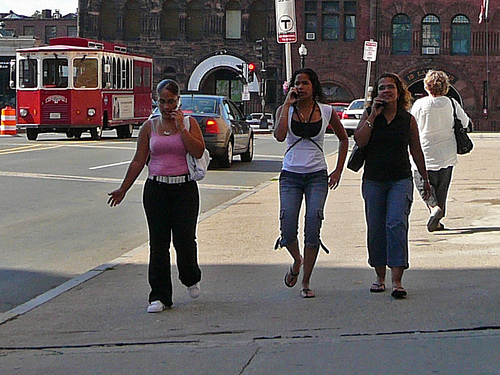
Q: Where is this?
A: This is at the sidewalk.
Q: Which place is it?
A: It is a sidewalk.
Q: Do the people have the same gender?
A: Yes, all the people are female.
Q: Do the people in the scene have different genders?
A: No, all the people are female.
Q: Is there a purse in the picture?
A: Yes, there is a purse.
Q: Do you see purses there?
A: Yes, there is a purse.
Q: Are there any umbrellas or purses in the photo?
A: Yes, there is a purse.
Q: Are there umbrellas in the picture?
A: No, there are no umbrellas.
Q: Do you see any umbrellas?
A: No, there are no umbrellas.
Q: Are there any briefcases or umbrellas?
A: No, there are no umbrellas or briefcases.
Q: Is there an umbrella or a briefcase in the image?
A: No, there are no umbrellas or briefcases.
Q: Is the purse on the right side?
A: Yes, the purse is on the right of the image.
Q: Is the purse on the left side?
A: No, the purse is on the right of the image.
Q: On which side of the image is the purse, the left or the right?
A: The purse is on the right of the image.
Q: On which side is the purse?
A: The purse is on the right of the image.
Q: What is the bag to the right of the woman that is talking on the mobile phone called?
A: The bag is a purse.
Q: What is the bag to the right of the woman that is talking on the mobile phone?
A: The bag is a purse.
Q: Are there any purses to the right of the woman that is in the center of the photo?
A: Yes, there is a purse to the right of the woman.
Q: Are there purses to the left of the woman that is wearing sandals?
A: No, the purse is to the right of the woman.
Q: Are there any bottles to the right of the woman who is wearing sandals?
A: No, there is a purse to the right of the woman.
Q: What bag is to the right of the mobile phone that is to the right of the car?
A: The bag is a purse.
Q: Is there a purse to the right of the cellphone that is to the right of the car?
A: Yes, there is a purse to the right of the cellphone.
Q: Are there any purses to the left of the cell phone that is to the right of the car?
A: No, the purse is to the right of the mobile phone.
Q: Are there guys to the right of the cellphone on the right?
A: No, there is a purse to the right of the mobile phone.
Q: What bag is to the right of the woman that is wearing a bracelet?
A: The bag is a purse.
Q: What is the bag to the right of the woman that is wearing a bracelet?
A: The bag is a purse.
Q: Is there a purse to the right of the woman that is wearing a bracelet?
A: Yes, there is a purse to the right of the woman.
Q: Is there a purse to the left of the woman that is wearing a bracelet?
A: No, the purse is to the right of the woman.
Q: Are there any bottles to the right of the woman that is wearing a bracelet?
A: No, there is a purse to the right of the woman.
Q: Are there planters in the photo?
A: No, there are no planters.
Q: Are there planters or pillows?
A: No, there are no planters or pillows.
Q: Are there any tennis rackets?
A: No, there are no tennis rackets.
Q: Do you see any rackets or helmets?
A: No, there are no rackets or helmets.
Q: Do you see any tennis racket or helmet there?
A: No, there are no rackets or helmets.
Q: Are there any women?
A: Yes, there is a woman.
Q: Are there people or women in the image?
A: Yes, there is a woman.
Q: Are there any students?
A: No, there are no students.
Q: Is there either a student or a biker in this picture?
A: No, there are no students or bikers.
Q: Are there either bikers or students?
A: No, there are no students or bikers.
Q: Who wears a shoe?
A: The woman wears a shoe.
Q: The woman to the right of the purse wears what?
A: The woman wears a shoe.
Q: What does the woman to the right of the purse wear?
A: The woman wears a shoe.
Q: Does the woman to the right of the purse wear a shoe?
A: Yes, the woman wears a shoe.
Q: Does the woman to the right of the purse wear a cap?
A: No, the woman wears a shoe.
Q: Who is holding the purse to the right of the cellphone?
A: The woman is holding the purse.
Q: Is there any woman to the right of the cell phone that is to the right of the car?
A: Yes, there is a woman to the right of the mobile phone.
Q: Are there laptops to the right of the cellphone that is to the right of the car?
A: No, there is a woman to the right of the mobile phone.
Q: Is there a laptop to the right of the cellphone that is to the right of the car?
A: No, there is a woman to the right of the mobile phone.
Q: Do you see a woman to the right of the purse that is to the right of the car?
A: Yes, there is a woman to the right of the purse.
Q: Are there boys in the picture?
A: No, there are no boys.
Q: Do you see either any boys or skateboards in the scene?
A: No, there are no boys or skateboards.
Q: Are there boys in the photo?
A: No, there are no boys.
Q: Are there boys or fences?
A: No, there are no boys or fences.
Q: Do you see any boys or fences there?
A: No, there are no boys or fences.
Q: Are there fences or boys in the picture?
A: No, there are no boys or fences.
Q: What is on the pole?
A: The sign is on the pole.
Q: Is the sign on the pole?
A: Yes, the sign is on the pole.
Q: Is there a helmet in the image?
A: No, there are no helmets.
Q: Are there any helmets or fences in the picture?
A: No, there are no helmets or fences.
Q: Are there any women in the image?
A: Yes, there is a woman.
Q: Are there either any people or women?
A: Yes, there is a woman.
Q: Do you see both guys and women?
A: No, there is a woman but no guys.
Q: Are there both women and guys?
A: No, there is a woman but no guys.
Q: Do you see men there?
A: No, there are no men.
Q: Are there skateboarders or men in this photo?
A: No, there are no men or skateboarders.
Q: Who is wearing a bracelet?
A: The woman is wearing a bracelet.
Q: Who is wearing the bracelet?
A: The woman is wearing a bracelet.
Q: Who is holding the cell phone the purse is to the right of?
A: The woman is holding the cell phone.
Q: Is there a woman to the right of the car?
A: Yes, there is a woman to the right of the car.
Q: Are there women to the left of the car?
A: No, the woman is to the right of the car.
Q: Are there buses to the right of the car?
A: No, there is a woman to the right of the car.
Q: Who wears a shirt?
A: The woman wears a shirt.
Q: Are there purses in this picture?
A: Yes, there is a purse.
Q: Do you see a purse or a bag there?
A: Yes, there is a purse.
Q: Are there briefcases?
A: No, there are no briefcases.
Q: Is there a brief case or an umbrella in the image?
A: No, there are no briefcases or umbrellas.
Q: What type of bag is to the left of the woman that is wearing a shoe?
A: The bag is a purse.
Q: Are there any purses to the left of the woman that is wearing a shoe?
A: Yes, there is a purse to the left of the woman.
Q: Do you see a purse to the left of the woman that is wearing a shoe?
A: Yes, there is a purse to the left of the woman.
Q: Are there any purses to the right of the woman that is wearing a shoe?
A: No, the purse is to the left of the woman.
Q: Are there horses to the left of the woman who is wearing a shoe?
A: No, there is a purse to the left of the woman.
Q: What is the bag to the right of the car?
A: The bag is a purse.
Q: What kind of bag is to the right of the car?
A: The bag is a purse.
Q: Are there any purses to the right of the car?
A: Yes, there is a purse to the right of the car.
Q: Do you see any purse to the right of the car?
A: Yes, there is a purse to the right of the car.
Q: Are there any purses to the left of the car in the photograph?
A: No, the purse is to the right of the car.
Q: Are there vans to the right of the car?
A: No, there is a purse to the right of the car.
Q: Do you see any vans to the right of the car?
A: No, there is a purse to the right of the car.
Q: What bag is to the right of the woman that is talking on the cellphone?
A: The bag is a purse.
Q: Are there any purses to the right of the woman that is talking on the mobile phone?
A: Yes, there is a purse to the right of the woman.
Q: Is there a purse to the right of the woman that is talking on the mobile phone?
A: Yes, there is a purse to the right of the woman.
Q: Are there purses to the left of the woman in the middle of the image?
A: No, the purse is to the right of the woman.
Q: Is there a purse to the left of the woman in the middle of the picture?
A: No, the purse is to the right of the woman.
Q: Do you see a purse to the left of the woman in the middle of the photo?
A: No, the purse is to the right of the woman.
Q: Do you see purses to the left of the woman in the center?
A: No, the purse is to the right of the woman.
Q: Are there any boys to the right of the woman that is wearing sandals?
A: No, there is a purse to the right of the woman.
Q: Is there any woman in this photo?
A: Yes, there is a woman.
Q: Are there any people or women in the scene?
A: Yes, there is a woman.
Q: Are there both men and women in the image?
A: No, there is a woman but no men.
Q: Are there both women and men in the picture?
A: No, there is a woman but no men.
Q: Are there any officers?
A: No, there are no officers.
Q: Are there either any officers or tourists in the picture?
A: No, there are no officers or tourists.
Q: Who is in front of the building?
A: The woman is in front of the building.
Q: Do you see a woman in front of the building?
A: Yes, there is a woman in front of the building.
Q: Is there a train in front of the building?
A: No, there is a woman in front of the building.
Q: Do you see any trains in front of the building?
A: No, there is a woman in front of the building.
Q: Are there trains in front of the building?
A: No, there is a woman in front of the building.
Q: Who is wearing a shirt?
A: The woman is wearing a shirt.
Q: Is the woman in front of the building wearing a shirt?
A: Yes, the woman is wearing a shirt.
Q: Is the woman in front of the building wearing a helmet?
A: No, the woman is wearing a shirt.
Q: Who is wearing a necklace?
A: The woman is wearing a necklace.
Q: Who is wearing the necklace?
A: The woman is wearing a necklace.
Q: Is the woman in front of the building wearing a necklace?
A: Yes, the woman is wearing a necklace.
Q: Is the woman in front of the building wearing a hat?
A: No, the woman is wearing a necklace.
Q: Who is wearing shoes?
A: The woman is wearing shoes.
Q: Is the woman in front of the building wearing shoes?
A: Yes, the woman is wearing shoes.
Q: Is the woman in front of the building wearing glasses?
A: No, the woman is wearing shoes.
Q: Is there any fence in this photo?
A: No, there are no fences.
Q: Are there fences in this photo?
A: No, there are no fences.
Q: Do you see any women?
A: Yes, there is a woman.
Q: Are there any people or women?
A: Yes, there is a woman.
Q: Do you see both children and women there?
A: No, there is a woman but no children.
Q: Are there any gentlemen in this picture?
A: No, there are no gentlemen.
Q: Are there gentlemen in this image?
A: No, there are no gentlemen.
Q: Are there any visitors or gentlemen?
A: No, there are no gentlemen or visitors.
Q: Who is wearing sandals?
A: The woman is wearing sandals.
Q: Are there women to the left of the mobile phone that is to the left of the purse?
A: Yes, there is a woman to the left of the cell phone.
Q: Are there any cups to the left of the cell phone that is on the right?
A: No, there is a woman to the left of the cell phone.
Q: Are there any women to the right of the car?
A: Yes, there is a woman to the right of the car.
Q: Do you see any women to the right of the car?
A: Yes, there is a woman to the right of the car.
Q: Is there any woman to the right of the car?
A: Yes, there is a woman to the right of the car.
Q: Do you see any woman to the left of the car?
A: No, the woman is to the right of the car.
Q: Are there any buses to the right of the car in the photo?
A: No, there is a woman to the right of the car.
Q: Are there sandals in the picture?
A: Yes, there are sandals.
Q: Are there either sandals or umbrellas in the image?
A: Yes, there are sandals.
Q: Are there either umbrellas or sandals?
A: Yes, there are sandals.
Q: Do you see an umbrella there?
A: No, there are no umbrellas.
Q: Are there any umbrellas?
A: No, there are no umbrellas.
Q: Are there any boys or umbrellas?
A: No, there are no umbrellas or boys.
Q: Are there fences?
A: No, there are no fences.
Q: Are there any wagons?
A: No, there are no wagons.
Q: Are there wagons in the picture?
A: No, there are no wagons.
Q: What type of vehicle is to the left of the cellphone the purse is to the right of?
A: The vehicle is a car.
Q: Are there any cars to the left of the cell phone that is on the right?
A: Yes, there is a car to the left of the mobile phone.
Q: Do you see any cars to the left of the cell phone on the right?
A: Yes, there is a car to the left of the mobile phone.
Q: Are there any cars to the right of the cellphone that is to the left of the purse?
A: No, the car is to the left of the cellphone.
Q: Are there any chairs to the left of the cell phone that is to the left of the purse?
A: No, there is a car to the left of the cell phone.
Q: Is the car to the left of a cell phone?
A: Yes, the car is to the left of a cell phone.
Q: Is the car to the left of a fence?
A: No, the car is to the left of a cell phone.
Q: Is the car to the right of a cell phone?
A: No, the car is to the left of a cell phone.